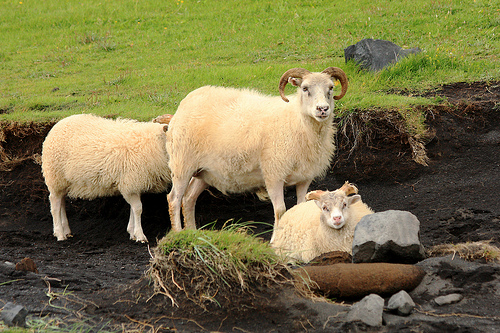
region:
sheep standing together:
[8, 31, 409, 293]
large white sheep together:
[4, 46, 399, 276]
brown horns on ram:
[271, 69, 309, 99]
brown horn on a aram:
[320, 62, 361, 103]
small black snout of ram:
[311, 101, 329, 125]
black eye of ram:
[298, 85, 316, 96]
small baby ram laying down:
[280, 182, 377, 257]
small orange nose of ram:
[332, 212, 346, 224]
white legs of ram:
[18, 183, 155, 264]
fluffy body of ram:
[45, 112, 170, 200]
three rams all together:
[18, 55, 420, 322]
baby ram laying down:
[270, 183, 375, 253]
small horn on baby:
[301, 188, 325, 205]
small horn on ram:
[341, 181, 361, 193]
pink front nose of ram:
[335, 215, 346, 219]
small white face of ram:
[314, 191, 361, 235]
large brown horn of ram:
[265, 69, 302, 100]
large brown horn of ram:
[328, 66, 355, 100]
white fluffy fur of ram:
[52, 109, 159, 196]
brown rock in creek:
[285, 256, 423, 298]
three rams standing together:
[10, 45, 402, 295]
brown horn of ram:
[264, 61, 311, 108]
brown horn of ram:
[332, 68, 347, 95]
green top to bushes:
[138, 209, 272, 316]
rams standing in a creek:
[1, 33, 395, 268]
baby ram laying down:
[258, 178, 383, 270]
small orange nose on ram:
[332, 215, 347, 223]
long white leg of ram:
[160, 178, 210, 243]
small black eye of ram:
[325, 73, 342, 95]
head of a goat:
[277, 42, 366, 125]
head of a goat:
[285, 155, 380, 250]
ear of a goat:
[276, 65, 308, 97]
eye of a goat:
[292, 78, 317, 98]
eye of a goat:
[320, 80, 344, 107]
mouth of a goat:
[308, 108, 334, 127]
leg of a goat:
[32, 174, 84, 244]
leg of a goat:
[103, 173, 155, 245]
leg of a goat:
[155, 199, 192, 255]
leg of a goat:
[253, 179, 295, 266]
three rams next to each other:
[38, 56, 380, 290]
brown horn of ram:
[330, 65, 352, 109]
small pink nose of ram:
[321, 108, 326, 113]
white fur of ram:
[178, 86, 298, 184]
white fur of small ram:
[48, 111, 182, 238]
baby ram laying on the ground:
[271, 185, 368, 249]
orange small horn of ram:
[340, 179, 360, 191]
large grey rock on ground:
[332, 216, 430, 270]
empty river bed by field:
[397, 156, 482, 294]